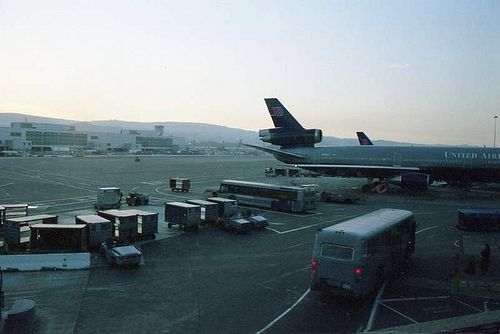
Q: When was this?
A: Daytime.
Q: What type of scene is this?
A: Outdoor.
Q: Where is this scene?
A: Airport.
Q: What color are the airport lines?
A: White.